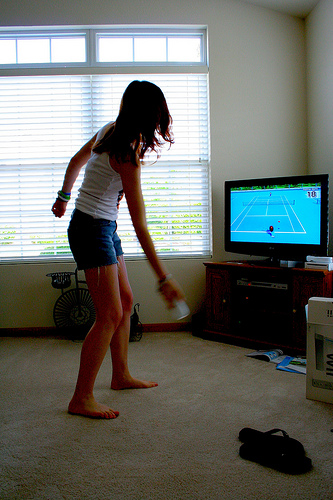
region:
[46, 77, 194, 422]
Girl playing video game.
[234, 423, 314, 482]
Black flip flops on floor.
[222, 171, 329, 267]
Black flat screen television.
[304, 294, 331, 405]
White opened box on floor.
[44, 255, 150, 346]
Black metal decoration on floor.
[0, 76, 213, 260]
White blinds on windows.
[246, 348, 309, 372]
A book with papers on the floor.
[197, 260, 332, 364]
Brown wood entertainment console.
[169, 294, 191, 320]
White game handle in girl's hand.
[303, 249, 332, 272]
White video game with controller on top.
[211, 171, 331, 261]
a large black t.v.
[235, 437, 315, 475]
a black shoe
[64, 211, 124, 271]
a girl's blue short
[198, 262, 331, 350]
a brown t.v. cabinet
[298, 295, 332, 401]
part of a white box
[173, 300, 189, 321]
part of a white game controller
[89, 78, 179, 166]
a girl's long hair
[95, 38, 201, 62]
a window of a home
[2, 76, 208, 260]
large white window blinds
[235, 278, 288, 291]
a long gray dvd player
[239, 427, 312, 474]
Pair of solid black flip flops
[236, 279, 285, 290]
Silver dvd player with red light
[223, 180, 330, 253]
Black flat screen tv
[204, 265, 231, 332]
Door on wooden tv stand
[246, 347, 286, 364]
Open book on floor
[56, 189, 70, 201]
Several bracelets on wrist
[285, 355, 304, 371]
Blue and white book on floor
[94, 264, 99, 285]
White fringe hanging on shorts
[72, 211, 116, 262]
Blue denim cut off shorts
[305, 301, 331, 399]
White game console box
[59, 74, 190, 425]
the girl is playing a game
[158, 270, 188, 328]
the girl is holding a controller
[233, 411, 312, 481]
a pair of black flip flops lay on the floor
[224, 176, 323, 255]
the girls game is displayed on the T.V.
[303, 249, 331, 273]
the gaming console sits next to the TV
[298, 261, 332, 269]
the console is a Wii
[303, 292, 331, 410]
this is the consoles box/packaging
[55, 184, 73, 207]
the girl is wearing bracelets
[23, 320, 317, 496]
the floor in this room is carpeted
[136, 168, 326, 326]
the girls game is a tennis game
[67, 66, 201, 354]
A girl playing the wii game.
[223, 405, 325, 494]
Black flip flops on the floor.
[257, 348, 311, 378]
A magazine on the carpet.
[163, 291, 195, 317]
A wii controller in the person hand.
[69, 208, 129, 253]
The person is wearing jean shorts.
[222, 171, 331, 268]
Television on the tv stand.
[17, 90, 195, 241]
White blinds on the window.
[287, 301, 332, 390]
A white box on the floor.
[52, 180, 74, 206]
The woman is wearing bracelets.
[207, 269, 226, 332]
Cabinet on the tv stand.